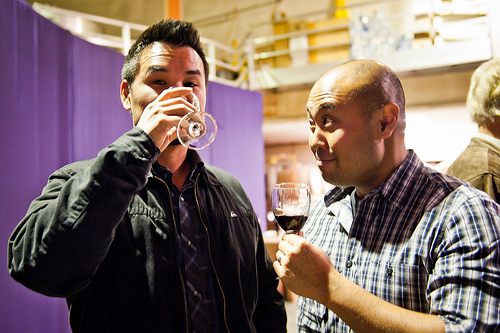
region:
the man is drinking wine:
[2, 11, 287, 331]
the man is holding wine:
[270, 55, 497, 330]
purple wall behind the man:
[6, 17, 286, 327]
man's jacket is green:
[7, 146, 282, 327]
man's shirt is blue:
[152, 160, 222, 327]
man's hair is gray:
[461, 55, 496, 120]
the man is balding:
[300, 55, 410, 190]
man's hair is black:
[112, 15, 214, 145]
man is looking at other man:
[270, 49, 499, 331]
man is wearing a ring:
[272, 253, 285, 263]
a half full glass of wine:
[268, 179, 316, 284]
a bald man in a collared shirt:
[260, 51, 498, 328]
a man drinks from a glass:
[16, 15, 273, 330]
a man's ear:
[376, 101, 403, 139]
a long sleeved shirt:
[7, 125, 300, 330]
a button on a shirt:
[342, 257, 354, 270]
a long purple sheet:
[1, 0, 277, 331]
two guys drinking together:
[7, 17, 498, 331]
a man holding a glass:
[271, 56, 493, 331]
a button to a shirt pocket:
[382, 264, 396, 276]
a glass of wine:
[271, 182, 313, 294]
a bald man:
[306, 58, 416, 185]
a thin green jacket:
[22, 144, 290, 331]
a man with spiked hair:
[122, 16, 217, 144]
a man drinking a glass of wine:
[121, 19, 216, 161]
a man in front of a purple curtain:
[0, 15, 274, 319]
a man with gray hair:
[465, 63, 499, 135]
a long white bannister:
[237, 20, 485, 82]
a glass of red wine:
[275, 180, 308, 236]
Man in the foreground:
[5, 10, 495, 330]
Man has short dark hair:
[110, 11, 221, 162]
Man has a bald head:
[290, 55, 425, 192]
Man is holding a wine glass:
[255, 177, 325, 304]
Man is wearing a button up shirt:
[255, 140, 498, 330]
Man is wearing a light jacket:
[3, 98, 290, 330]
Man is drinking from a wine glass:
[126, 83, 227, 158]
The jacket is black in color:
[2, 118, 289, 330]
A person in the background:
[440, 47, 496, 197]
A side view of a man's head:
[276, 49, 432, 193]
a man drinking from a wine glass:
[96, 24, 247, 285]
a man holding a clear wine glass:
[257, 67, 483, 325]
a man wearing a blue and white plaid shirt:
[273, 67, 496, 322]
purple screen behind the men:
[8, 41, 83, 172]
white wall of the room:
[421, 107, 463, 155]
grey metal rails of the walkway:
[225, 22, 347, 91]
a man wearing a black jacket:
[17, 56, 285, 324]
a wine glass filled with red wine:
[269, 180, 313, 233]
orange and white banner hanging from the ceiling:
[153, 0, 190, 25]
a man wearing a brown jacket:
[433, 52, 498, 211]